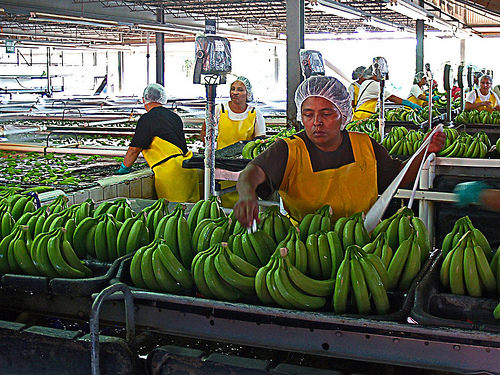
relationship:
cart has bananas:
[0, 243, 499, 375] [231, 223, 276, 270]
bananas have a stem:
[231, 223, 276, 270] [238, 224, 252, 234]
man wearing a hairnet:
[233, 74, 447, 225] [295, 74, 354, 129]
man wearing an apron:
[233, 74, 447, 225] [279, 133, 380, 221]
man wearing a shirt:
[118, 83, 204, 206] [129, 110, 187, 155]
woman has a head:
[203, 75, 266, 146] [230, 75, 254, 107]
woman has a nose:
[203, 75, 266, 146] [233, 90, 237, 95]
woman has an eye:
[203, 75, 266, 146] [239, 87, 246, 91]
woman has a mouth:
[203, 75, 266, 146] [233, 96, 241, 99]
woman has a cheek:
[203, 75, 266, 146] [238, 92, 247, 97]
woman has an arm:
[203, 75, 266, 146] [255, 110, 266, 138]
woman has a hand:
[233, 74, 447, 225] [230, 198, 261, 228]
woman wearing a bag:
[203, 75, 266, 146] [237, 76, 254, 102]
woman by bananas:
[233, 74, 447, 225] [231, 223, 276, 270]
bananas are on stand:
[231, 223, 276, 270] [0, 243, 499, 375]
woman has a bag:
[233, 74, 447, 225] [359, 120, 444, 231]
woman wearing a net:
[203, 75, 266, 146] [237, 76, 254, 102]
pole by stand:
[203, 85, 217, 200] [0, 243, 499, 375]